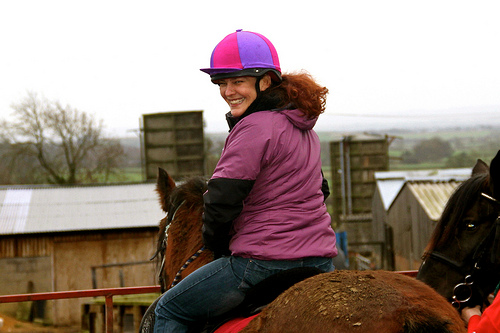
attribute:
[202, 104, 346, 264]
t shirt — purple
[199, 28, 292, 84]
hat — pink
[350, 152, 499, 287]
rooftops — angled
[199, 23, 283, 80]
hat — pink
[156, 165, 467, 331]
horse — brown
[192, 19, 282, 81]
helmet — pink, purple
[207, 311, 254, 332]
saddle — red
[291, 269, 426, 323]
back — dirty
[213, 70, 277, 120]
skin — light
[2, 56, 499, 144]
sky — blue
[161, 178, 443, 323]
horse — brown